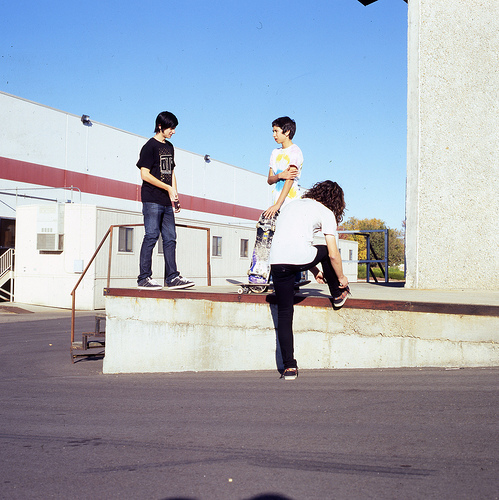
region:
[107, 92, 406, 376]
young people on a sloped platform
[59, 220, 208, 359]
railing and steps leading to platform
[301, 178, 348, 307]
person bending forward to tie shoe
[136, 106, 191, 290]
young man standing on edge of slope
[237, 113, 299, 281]
teen holding skateboard and elbow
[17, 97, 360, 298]
white building with reddish stripe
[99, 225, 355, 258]
small windows along side of building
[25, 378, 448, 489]
asphalt ground with dark lines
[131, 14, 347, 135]
clear blue sky behind teens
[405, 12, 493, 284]
rough texture of wall behind slope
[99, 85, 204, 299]
a person walking toward a wall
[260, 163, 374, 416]
a person tying his shoes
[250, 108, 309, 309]
a person holding a skateboard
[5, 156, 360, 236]
a red stripe on a building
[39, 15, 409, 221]
a clear blue sky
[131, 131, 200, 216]
a black t-shirt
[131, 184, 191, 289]
a pair of blue jeans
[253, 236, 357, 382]
a pair of black pants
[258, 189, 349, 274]
a white t-shirt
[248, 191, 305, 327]
a black and silver skateboard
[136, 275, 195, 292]
black and white sneakers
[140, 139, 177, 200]
black and white tee shirt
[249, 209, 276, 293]
black and white skate board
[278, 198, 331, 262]
white cotton tee shirt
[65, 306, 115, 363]
grey stone stairs to platform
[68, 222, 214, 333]
orange painted railing on steps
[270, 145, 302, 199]
yellow white and blue tee shirt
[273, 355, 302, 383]
red black and white sneaker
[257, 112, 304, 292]
girl holding skate board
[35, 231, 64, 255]
air conditioner in window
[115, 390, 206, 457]
this is the ground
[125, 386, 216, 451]
the ground is grey in color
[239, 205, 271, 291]
this is a skateboard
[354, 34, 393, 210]
this is the sky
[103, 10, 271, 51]
the sky is blue in color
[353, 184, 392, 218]
the sky has some clouds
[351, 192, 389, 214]
the clouds are white in color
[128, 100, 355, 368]
these are some people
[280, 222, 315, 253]
the t-shirt is white in color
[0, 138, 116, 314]
this is a building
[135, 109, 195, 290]
the boy standing wearing a black shirt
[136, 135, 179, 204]
the short sleeved black shirt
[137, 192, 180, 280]
the pair of denim jeans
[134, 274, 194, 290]
the dark colored pair of shoes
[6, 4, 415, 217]
the clear blue sky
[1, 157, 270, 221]
the red line on the building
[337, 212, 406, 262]
the trees in the distance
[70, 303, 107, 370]
the metal staircase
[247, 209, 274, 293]
the skateboard the boy's holding up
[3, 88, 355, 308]
the big white building